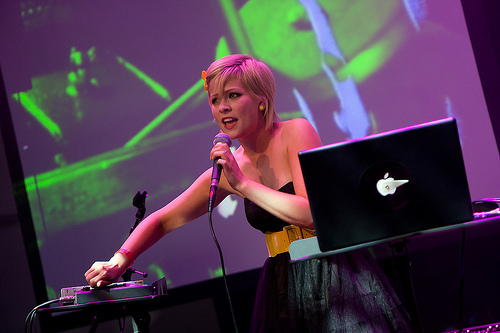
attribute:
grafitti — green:
[9, 3, 429, 248]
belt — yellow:
[262, 221, 317, 259]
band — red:
[88, 227, 128, 283]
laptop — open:
[234, 150, 483, 235]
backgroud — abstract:
[261, 0, 465, 165]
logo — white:
[351, 160, 419, 228]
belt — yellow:
[232, 220, 281, 242]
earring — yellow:
[242, 90, 269, 112]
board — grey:
[39, 248, 150, 329]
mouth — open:
[202, 95, 307, 199]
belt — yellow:
[218, 193, 390, 313]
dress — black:
[220, 188, 349, 278]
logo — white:
[344, 161, 430, 236]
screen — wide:
[127, 62, 278, 165]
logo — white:
[338, 159, 407, 215]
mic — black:
[216, 133, 276, 234]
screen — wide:
[20, 19, 351, 202]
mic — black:
[197, 103, 246, 182]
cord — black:
[131, 177, 282, 327]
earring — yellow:
[235, 110, 283, 134]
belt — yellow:
[231, 210, 394, 313]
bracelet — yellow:
[218, 140, 256, 208]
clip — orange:
[186, 65, 246, 120]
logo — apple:
[371, 167, 400, 198]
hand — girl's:
[207, 141, 243, 188]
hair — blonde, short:
[199, 51, 280, 129]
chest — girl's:
[227, 125, 291, 197]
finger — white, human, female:
[214, 155, 230, 167]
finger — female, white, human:
[210, 144, 228, 159]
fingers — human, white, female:
[209, 140, 229, 169]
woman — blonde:
[80, 54, 422, 330]